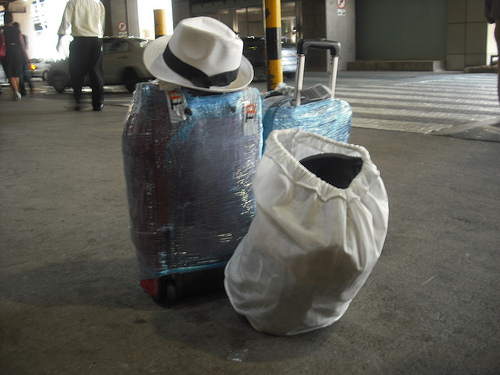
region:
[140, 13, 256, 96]
white and black fedora hat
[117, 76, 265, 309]
blue wrapped suitcase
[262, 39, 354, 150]
blue wrapped suitcase with handle up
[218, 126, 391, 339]
white bag by the suitcases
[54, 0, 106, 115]
man with white shirt and black pants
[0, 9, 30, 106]
woman wearing black dress, walking away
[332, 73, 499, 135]
white and gray crosswalk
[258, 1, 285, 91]
black and yellow pillar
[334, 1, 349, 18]
white, red and black circle sign on the wall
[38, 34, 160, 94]
white car driving away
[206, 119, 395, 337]
a white bag of clothes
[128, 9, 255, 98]
a white hat with black ribbon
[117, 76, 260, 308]
plastic wrapped red luggage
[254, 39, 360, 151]
plastic wrapped grey luggage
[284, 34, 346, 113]
extendable luggage handle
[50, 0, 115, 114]
a man standing by curb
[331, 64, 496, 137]
a white cross walk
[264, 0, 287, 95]
a yellow and black pole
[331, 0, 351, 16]
a no parking sign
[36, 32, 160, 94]
a moving white car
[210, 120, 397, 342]
A white bag.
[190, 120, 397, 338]
The bag is made of cloth.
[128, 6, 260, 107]
A hat.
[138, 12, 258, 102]
The hat is white.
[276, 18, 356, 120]
This luggage has a handle.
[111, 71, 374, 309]
A group of luggage.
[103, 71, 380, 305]
The luggage is red.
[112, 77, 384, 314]
The luggage is wrapped in plastic.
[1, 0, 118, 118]
People are in the background.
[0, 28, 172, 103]
Cars are in the background.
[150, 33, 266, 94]
mans hat on top of a suitcase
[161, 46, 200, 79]
black band on a mans hat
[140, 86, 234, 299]
suitcase wrapped up in plastic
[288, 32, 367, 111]
handle of a suitcase wrapped in plastic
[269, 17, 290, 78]
traffic pole in the car area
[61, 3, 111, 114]
a man walking in the parking garage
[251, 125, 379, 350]
white duffle bag full of clothing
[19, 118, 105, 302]
cement walkway in the parking garage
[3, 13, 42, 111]
a woman walking in the parking garage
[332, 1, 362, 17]
do not smoke sign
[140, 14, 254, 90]
A gray and black hat.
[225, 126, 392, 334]
A small cotton white sack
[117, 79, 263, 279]
A blue shrink wrapped suitcase with a hat on it.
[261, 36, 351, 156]
A suitcase with an extendable handle.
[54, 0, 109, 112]
A man in black pants with a long sleeve white shirt.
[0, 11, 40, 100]
Two people walking to the left of a man in black pants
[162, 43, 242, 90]
Black band on a gray hat.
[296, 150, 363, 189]
Black item inside a white sack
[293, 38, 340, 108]
Silver and black extendable handle on a suitcase.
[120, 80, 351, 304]
Shrink wrapped luggage.